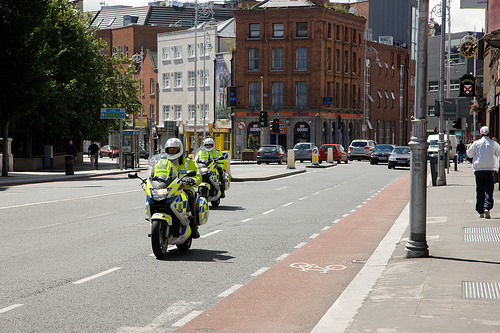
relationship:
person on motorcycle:
[144, 137, 202, 238] [128, 170, 211, 258]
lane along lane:
[244, 296, 347, 325] [244, 296, 347, 325]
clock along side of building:
[458, 41, 477, 56] [476, 1, 496, 96]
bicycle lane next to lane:
[150, 171, 409, 328] [244, 296, 347, 325]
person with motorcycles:
[144, 137, 202, 238] [128, 157, 232, 257]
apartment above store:
[242, 78, 310, 105] [224, 112, 351, 163]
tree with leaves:
[1, 2, 145, 154] [27, 0, 141, 132]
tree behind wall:
[1, 2, 145, 154] [0, 137, 86, 169]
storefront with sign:
[184, 120, 233, 162] [180, 120, 210, 135]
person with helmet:
[144, 137, 202, 238] [162, 137, 182, 158]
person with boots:
[144, 137, 202, 238] [186, 216, 201, 240]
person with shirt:
[466, 126, 499, 219] [84, 142, 102, 158]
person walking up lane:
[466, 126, 499, 219] [244, 296, 347, 325]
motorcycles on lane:
[68, 104, 328, 291] [244, 296, 347, 325]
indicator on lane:
[290, 262, 347, 274] [244, 296, 347, 325]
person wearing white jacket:
[462, 124, 484, 208] [465, 136, 499, 172]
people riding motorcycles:
[141, 137, 226, 238] [128, 157, 232, 257]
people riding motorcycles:
[156, 137, 198, 239] [128, 157, 232, 257]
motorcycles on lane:
[128, 157, 232, 257] [244, 296, 347, 325]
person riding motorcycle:
[152, 135, 192, 208] [128, 170, 211, 258]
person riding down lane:
[152, 135, 192, 208] [244, 296, 347, 325]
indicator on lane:
[290, 262, 347, 274] [267, 221, 347, 325]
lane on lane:
[267, 221, 347, 325] [244, 296, 347, 325]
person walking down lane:
[466, 126, 499, 219] [244, 296, 347, 325]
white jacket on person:
[465, 134, 499, 171] [466, 126, 499, 219]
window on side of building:
[296, 45, 306, 69] [228, 5, 365, 163]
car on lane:
[318, 142, 349, 163] [244, 296, 347, 325]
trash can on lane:
[62, 144, 91, 184] [244, 296, 347, 325]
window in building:
[297, 46, 309, 71] [228, 5, 365, 163]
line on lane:
[313, 189, 321, 195] [244, 296, 347, 325]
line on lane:
[262, 208, 273, 215] [244, 296, 347, 325]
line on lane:
[242, 213, 256, 222] [244, 296, 347, 325]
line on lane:
[200, 227, 220, 239] [244, 296, 347, 325]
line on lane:
[72, 266, 118, 286] [244, 296, 347, 325]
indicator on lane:
[285, 252, 345, 280] [244, 296, 347, 325]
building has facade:
[149, 21, 231, 161] [163, 41, 208, 116]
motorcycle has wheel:
[145, 166, 205, 254] [202, 185, 204, 194]